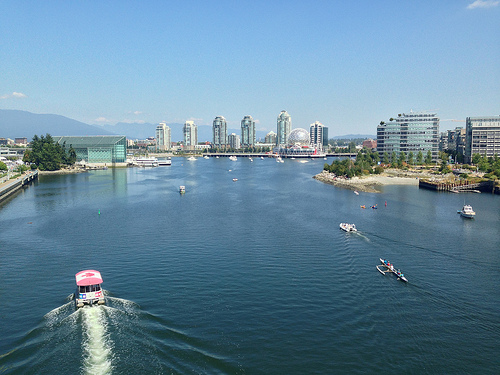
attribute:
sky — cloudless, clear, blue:
[0, 2, 499, 141]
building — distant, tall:
[276, 109, 293, 150]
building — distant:
[239, 113, 257, 148]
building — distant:
[211, 114, 230, 148]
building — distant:
[181, 119, 198, 147]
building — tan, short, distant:
[154, 121, 172, 153]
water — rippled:
[0, 158, 499, 373]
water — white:
[45, 297, 140, 374]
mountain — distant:
[1, 108, 118, 138]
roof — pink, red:
[76, 266, 103, 288]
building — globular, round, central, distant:
[287, 127, 311, 149]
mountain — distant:
[96, 119, 274, 143]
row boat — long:
[375, 255, 409, 287]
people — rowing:
[381, 258, 405, 279]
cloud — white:
[9, 89, 30, 101]